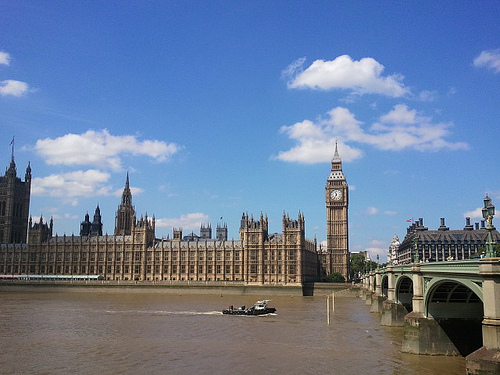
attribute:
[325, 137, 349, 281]
clocktower — huge, big, brown, tall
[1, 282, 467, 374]
water — brown, muddy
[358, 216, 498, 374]
bridge — green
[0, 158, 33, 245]
building — brown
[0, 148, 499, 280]
buildings — old, brown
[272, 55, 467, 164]
clouds — puffy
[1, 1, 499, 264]
sky — blue, clear